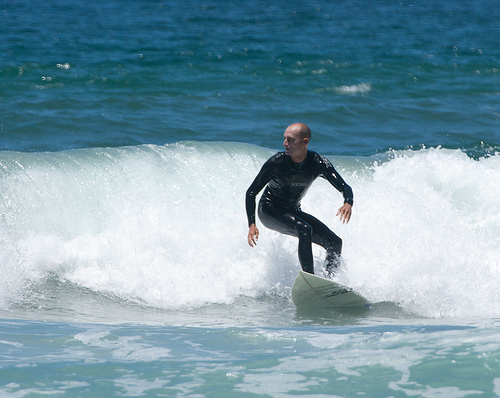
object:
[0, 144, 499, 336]
wave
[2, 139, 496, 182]
top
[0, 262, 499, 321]
bottom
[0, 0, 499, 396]
ocean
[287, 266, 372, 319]
board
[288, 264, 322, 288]
tip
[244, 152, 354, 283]
suit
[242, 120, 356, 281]
man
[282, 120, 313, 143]
hair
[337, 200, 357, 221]
hand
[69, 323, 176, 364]
foam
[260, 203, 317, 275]
leg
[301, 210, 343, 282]
leg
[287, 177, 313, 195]
xcel